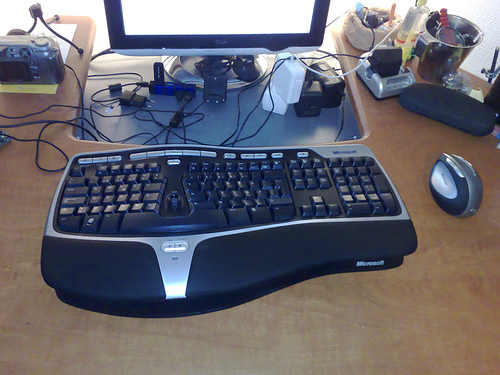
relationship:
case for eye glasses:
[406, 75, 485, 136] [409, 82, 485, 124]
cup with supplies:
[405, 18, 485, 94] [424, 13, 472, 43]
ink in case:
[378, 0, 429, 57] [402, 5, 418, 73]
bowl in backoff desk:
[345, 8, 403, 52] [0, 21, 499, 374]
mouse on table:
[426, 152, 484, 218] [18, 40, 485, 352]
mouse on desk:
[425, 152, 485, 212] [0, 21, 499, 374]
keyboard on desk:
[64, 150, 394, 227] [14, 25, 479, 361]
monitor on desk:
[122, 2, 319, 40] [14, 25, 479, 361]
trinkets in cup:
[432, 10, 466, 44] [422, 12, 469, 92]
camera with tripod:
[10, 37, 60, 87] [9, 4, 81, 48]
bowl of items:
[345, 5, 403, 52] [358, 4, 397, 28]